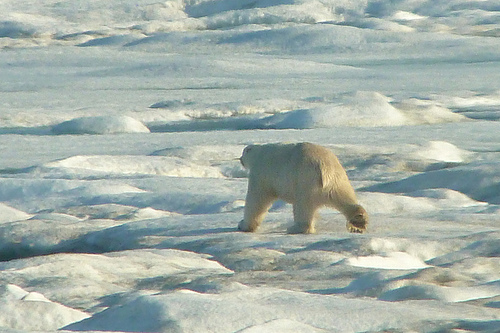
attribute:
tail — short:
[313, 162, 330, 192]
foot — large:
[340, 205, 370, 237]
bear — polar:
[234, 141, 372, 238]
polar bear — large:
[235, 141, 369, 239]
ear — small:
[242, 143, 252, 153]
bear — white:
[194, 79, 401, 315]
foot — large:
[287, 214, 323, 234]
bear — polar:
[216, 145, 376, 249]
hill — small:
[58, 111, 148, 132]